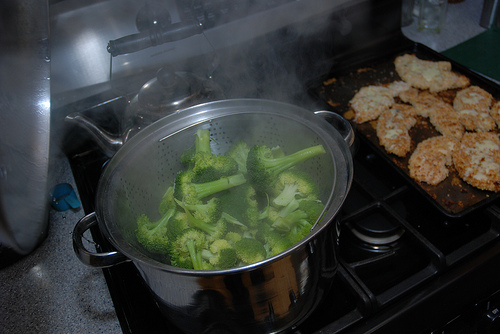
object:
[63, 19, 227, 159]
kettle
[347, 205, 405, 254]
burner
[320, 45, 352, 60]
ground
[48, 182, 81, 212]
blue cup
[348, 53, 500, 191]
breaded meat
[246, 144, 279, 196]
leaf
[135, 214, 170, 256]
leaf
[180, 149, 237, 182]
leaf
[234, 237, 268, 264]
leaf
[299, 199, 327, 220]
leaf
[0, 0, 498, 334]
kitchen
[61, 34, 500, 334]
stove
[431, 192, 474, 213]
crumbs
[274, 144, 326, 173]
stem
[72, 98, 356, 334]
cook pot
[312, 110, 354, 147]
handle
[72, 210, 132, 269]
handle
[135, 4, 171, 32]
button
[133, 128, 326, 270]
broccoli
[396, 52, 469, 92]
food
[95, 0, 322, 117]
smoke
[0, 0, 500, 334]
top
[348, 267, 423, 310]
part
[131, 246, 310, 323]
reflection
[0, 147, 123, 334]
counter top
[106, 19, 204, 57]
handle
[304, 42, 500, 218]
pan